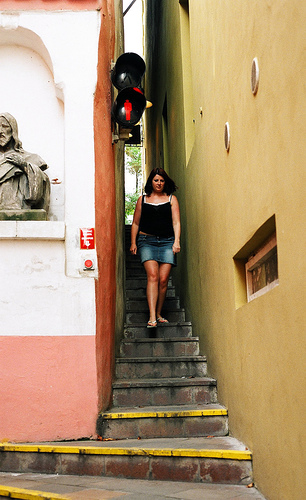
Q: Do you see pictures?
A: No, there are no pictures.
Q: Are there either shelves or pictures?
A: No, there are no pictures or shelves.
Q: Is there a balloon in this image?
A: Yes, there is a balloon.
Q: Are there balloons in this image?
A: Yes, there is a balloon.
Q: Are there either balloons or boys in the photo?
A: Yes, there is a balloon.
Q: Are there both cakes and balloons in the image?
A: No, there is a balloon but no cakes.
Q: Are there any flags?
A: No, there are no flags.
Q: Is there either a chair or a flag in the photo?
A: No, there are no flags or chairs.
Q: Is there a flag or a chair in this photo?
A: No, there are no flags or chairs.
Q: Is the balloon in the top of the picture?
A: Yes, the balloon is in the top of the image.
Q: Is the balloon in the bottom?
A: No, the balloon is in the top of the image.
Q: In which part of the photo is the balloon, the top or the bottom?
A: The balloon is in the top of the image.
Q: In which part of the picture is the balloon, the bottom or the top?
A: The balloon is in the top of the image.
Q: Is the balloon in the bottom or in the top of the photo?
A: The balloon is in the top of the image.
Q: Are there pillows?
A: No, there are no pillows.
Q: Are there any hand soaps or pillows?
A: No, there are no pillows or hand soaps.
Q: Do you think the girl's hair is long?
A: Yes, the hair is long.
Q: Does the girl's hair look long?
A: Yes, the hair is long.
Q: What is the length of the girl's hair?
A: The hair is long.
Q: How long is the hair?
A: The hair is long.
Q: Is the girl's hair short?
A: No, the hair is long.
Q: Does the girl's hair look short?
A: No, the hair is long.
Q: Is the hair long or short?
A: The hair is long.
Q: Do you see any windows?
A: Yes, there is a window.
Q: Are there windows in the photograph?
A: Yes, there is a window.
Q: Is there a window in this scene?
A: Yes, there is a window.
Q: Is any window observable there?
A: Yes, there is a window.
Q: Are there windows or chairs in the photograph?
A: Yes, there is a window.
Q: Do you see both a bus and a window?
A: No, there is a window but no buses.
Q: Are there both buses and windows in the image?
A: No, there is a window but no buses.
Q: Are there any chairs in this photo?
A: No, there are no chairs.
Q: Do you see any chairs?
A: No, there are no chairs.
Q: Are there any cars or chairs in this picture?
A: No, there are no chairs or cars.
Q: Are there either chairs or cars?
A: No, there are no chairs or cars.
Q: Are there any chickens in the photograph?
A: No, there are no chickens.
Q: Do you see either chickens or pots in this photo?
A: No, there are no chickens or pots.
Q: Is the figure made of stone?
A: Yes, the figure is made of stone.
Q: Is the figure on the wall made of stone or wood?
A: The figure is made of stone.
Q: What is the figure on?
A: The figure is on the wall.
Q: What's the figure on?
A: The figure is on the wall.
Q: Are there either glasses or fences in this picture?
A: No, there are no fences or glasses.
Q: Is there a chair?
A: No, there are no chairs.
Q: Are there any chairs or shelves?
A: No, there are no chairs or shelves.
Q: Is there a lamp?
A: Yes, there is a lamp.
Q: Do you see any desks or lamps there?
A: Yes, there is a lamp.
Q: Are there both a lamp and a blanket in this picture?
A: No, there is a lamp but no blankets.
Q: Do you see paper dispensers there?
A: No, there are no paper dispensers.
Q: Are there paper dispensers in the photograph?
A: No, there are no paper dispensers.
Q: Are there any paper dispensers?
A: No, there are no paper dispensers.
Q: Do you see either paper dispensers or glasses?
A: No, there are no paper dispensers or glasses.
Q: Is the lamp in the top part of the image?
A: Yes, the lamp is in the top of the image.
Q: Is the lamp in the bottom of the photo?
A: No, the lamp is in the top of the image.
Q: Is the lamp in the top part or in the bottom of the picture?
A: The lamp is in the top of the image.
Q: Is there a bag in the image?
A: No, there are no bags.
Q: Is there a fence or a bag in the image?
A: No, there are no bags or fences.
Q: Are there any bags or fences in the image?
A: No, there are no bags or fences.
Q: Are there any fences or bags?
A: No, there are no bags or fences.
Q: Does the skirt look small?
A: Yes, the skirt is small.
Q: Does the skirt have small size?
A: Yes, the skirt is small.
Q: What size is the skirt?
A: The skirt is small.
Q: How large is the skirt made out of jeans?
A: The skirt is small.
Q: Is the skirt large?
A: No, the skirt is small.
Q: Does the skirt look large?
A: No, the skirt is small.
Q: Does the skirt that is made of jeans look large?
A: No, the skirt is small.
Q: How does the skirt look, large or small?
A: The skirt is small.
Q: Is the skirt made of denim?
A: Yes, the skirt is made of denim.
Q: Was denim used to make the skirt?
A: Yes, the skirt is made of denim.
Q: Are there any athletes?
A: No, there are no athletes.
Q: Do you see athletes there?
A: No, there are no athletes.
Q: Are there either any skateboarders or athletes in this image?
A: No, there are no athletes or skateboarders.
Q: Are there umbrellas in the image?
A: No, there are no umbrellas.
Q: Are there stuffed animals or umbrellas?
A: No, there are no umbrellas or stuffed animals.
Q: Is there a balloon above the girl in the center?
A: Yes, there are balloons above the girl.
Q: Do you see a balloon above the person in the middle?
A: Yes, there are balloons above the girl.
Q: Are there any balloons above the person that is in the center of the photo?
A: Yes, there are balloons above the girl.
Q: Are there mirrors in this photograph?
A: No, there are no mirrors.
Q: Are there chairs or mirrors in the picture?
A: No, there are no mirrors or chairs.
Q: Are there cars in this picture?
A: No, there are no cars.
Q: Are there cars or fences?
A: No, there are no cars or fences.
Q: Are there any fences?
A: No, there are no fences.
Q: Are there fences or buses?
A: No, there are no fences or buses.